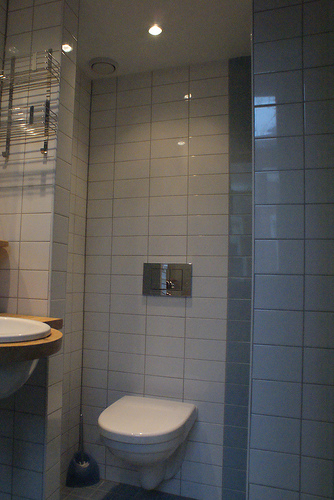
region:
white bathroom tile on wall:
[113, 120, 155, 141]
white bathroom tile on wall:
[253, 440, 304, 491]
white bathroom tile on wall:
[107, 293, 150, 312]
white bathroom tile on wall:
[151, 85, 196, 101]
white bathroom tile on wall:
[103, 328, 143, 353]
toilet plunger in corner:
[66, 394, 99, 490]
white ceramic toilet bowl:
[92, 379, 204, 487]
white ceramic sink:
[1, 304, 60, 407]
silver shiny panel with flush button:
[140, 260, 200, 301]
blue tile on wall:
[228, 316, 252, 344]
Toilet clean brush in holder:
[76, 411, 87, 468]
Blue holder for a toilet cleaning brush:
[67, 452, 100, 488]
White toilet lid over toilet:
[95, 388, 198, 441]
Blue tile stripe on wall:
[217, 346, 246, 499]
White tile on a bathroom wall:
[88, 83, 226, 256]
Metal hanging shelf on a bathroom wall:
[1, 55, 55, 159]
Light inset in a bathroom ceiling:
[146, 21, 164, 39]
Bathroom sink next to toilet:
[0, 310, 64, 404]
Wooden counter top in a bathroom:
[0, 239, 10, 248]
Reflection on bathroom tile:
[250, 95, 278, 277]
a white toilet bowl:
[88, 387, 201, 496]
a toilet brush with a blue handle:
[70, 409, 89, 469]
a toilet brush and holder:
[69, 405, 92, 487]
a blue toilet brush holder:
[71, 451, 96, 483]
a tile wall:
[251, 277, 306, 489]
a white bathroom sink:
[1, 303, 71, 355]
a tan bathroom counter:
[0, 310, 66, 381]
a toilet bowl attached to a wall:
[107, 372, 209, 496]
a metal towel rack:
[0, 48, 64, 175]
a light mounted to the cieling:
[120, 24, 180, 50]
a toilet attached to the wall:
[92, 381, 203, 492]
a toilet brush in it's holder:
[65, 399, 103, 491]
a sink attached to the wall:
[1, 309, 67, 407]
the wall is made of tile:
[86, 75, 233, 256]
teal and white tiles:
[188, 56, 250, 412]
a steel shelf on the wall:
[0, 42, 62, 158]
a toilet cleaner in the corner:
[65, 384, 105, 492]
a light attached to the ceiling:
[121, 12, 184, 62]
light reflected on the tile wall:
[52, 36, 78, 63]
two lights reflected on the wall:
[160, 83, 201, 152]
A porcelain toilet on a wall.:
[92, 383, 196, 493]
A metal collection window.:
[138, 256, 193, 303]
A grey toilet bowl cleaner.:
[67, 407, 101, 489]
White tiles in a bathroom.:
[90, 167, 232, 260]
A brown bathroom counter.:
[3, 311, 65, 362]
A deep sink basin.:
[0, 313, 52, 402]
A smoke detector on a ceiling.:
[89, 52, 122, 83]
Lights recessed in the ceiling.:
[140, 17, 167, 43]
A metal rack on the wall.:
[3, 45, 63, 170]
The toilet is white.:
[86, 391, 199, 493]